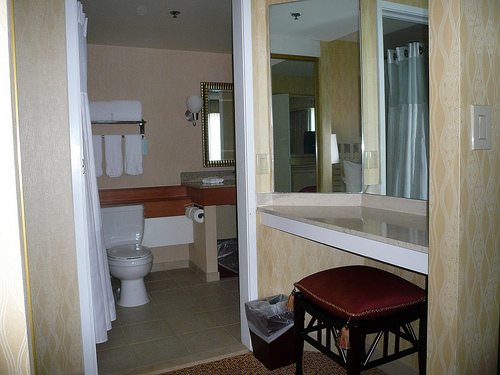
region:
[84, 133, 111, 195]
white towel hanging on rod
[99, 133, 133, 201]
white towel hanging on rod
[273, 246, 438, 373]
small stool for sitting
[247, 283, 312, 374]
small wastebasket near door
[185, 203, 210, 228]
toilet paper roll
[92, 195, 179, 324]
white ceramic toilet bowl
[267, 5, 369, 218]
large mirror on wall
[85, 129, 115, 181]
white towel hanging on rod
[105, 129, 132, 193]
white towel hanging on rod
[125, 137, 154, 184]
white towel hanging on rod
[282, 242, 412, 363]
small stool for sitting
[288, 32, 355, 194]
reflection of giant mirror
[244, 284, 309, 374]
small black wastebasket near door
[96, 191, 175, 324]
white ceramic toilet bowl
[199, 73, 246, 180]
rectangular mirror on wall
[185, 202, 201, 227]
toilet paper roll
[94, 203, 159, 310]
Clean white toilet bowl with seat down.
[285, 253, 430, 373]
Black stool with red pillow on it.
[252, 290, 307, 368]
Black garbage can with garbage bag in it.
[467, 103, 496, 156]
Rectangular beige light switch.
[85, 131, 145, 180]
Three white towels hanging on towel rack.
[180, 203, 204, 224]
Two full rolls of toilet paper.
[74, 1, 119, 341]
White shower curtains hanging.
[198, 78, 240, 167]
Bathroom mirror with gold frame.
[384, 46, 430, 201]
Reflection of white bathroom curtain.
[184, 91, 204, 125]
Single unlit light fixture.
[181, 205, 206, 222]
toilet paper in the bathroom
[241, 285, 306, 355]
waste bin beside the stool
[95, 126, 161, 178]
towels hanging above the toilet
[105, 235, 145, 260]
the toilet lid is down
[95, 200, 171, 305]
the toilet is white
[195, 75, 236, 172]
the mirror on the wall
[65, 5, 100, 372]
the door is open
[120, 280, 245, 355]
the bathroom floor is tiled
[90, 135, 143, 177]
the towels are white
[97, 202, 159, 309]
Clean white toilet bowl.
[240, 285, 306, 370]
Black garbage can with trash bag.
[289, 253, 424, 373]
Black stool with red pillow on it.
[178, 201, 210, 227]
Two full rolls of toilet paper side by side.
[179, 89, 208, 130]
One unlit light fixture.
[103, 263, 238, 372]
Beige square bathroom tile.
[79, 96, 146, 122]
Two folded white bathroom towels.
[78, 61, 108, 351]
White shower curtain hanging.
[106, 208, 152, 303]
a white toilet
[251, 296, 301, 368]
a black trash bin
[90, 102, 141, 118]
white towels on a shelf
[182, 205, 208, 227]
Two rolls of white toilet paper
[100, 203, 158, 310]
A white toilet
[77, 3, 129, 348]
A white shower curtain hanging up.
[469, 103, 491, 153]
A light switch panel on the wall.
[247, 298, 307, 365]
A dark colored trash bin.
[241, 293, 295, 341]
A clear trash bag.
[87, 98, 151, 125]
Folded towels on a towel rack.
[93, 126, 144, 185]
Towels hanging on a towel rack.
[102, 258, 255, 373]
Beige tile flooring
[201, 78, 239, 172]
A gold framed mirror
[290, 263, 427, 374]
a stool with a red pillow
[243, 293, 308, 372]
a trash can near a black stool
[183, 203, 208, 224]
rolls of toilet paper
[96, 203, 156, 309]
a white porcelain toilet